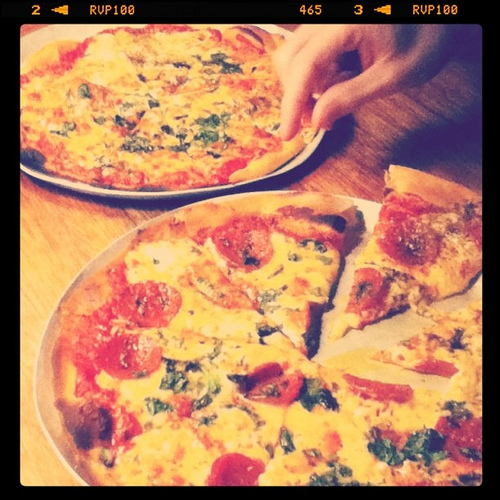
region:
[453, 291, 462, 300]
part of a pizza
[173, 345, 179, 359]
edge of a plate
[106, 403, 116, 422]
part of an onion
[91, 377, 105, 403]
edge of a plate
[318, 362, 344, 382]
part of a tomato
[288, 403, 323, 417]
part of a pineapple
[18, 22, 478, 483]
Two medium pizzas on plates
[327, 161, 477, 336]
A slice of pepperoni pizza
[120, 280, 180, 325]
A slice of pepperoni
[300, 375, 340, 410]
A small bit of parsley on a pizza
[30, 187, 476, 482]
A white plate with a pizza on it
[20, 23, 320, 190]
A medium cheese pizza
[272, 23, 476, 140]
A person's hand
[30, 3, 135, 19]
Text that reads "2 < RUP100"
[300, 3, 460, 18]
Text that reads "465 3 < RUP100"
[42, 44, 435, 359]
two pizzas on a plate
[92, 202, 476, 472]
a pizza on a platter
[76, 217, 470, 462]
a pepperoni pizza on a tray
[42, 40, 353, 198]
this pizza is on a dish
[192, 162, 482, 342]
two slices of pizza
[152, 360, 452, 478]
garnishments on a pizza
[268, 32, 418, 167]
a hand is about to get a slice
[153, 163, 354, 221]
golden crust on the pizzas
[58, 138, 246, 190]
res sauce on the pizza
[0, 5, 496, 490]
a black border around the edge of picture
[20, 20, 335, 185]
a pizza on a table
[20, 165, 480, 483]
a pizza at the bottom of the picture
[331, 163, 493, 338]
a pizza slice removed from the pie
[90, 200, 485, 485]
a pepperoni pizza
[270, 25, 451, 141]
person reaching out to take a slice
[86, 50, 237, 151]
spinach on the top pizza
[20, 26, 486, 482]
pizza is sitting on wooden table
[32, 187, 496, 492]
pizza is on an alumnium pizza plate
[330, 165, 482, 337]
a slice of pizza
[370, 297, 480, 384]
a slice of pizza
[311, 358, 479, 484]
a slice of pizza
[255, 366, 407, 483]
a slice of pizza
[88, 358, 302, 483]
a slice of pizza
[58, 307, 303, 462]
a slice of pizza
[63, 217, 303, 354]
a slice of pizza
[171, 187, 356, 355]
a slice of pizza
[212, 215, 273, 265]
a red slice of pepperoni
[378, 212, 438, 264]
a red slice of pepperoni